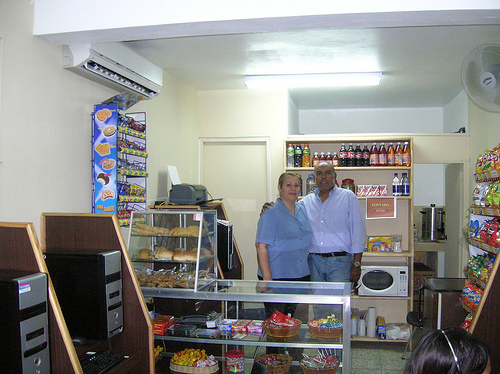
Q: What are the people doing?
A: Holding each other.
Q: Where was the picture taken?
A: In a shop.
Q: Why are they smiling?
A: They are happy.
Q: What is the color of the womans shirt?
A: Blue.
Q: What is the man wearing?
A: Watch.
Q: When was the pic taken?
A: During the day.